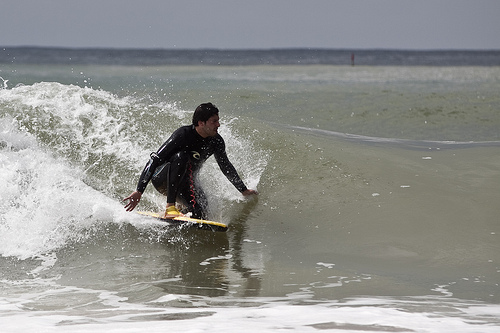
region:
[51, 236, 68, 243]
a drop of water in the ocean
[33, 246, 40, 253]
a drop of water in the ocean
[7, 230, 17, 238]
a drop of water in the ocean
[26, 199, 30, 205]
a drop of water in the ocean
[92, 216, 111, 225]
a drop of water in the ocean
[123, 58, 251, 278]
the man is surfing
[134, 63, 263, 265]
the man is surfing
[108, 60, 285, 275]
the man is surfing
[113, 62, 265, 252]
the man is surfing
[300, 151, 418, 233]
the water is murky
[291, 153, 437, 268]
the water is murky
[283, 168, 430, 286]
the water is murky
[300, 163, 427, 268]
the water is murky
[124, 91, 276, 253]
The man is kneeling on the board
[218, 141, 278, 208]
The man's hand is in the water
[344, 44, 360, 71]
The buoy that is far away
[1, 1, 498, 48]
The sky looks like it is going to rain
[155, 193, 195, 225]
The man is wearing yellow shoes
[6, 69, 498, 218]
the wave the man is riding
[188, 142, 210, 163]
The logo on the wet suit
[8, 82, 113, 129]
The white foam from the wave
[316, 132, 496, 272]
The water is that smooth and calm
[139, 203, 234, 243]
The surfboard is yellow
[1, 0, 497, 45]
blue of daytime sky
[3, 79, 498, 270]
swelling wave in ocean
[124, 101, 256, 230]
kneeling man on surfboard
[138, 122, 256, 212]
black wetsuit on surfer's body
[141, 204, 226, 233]
foot on top of surfboard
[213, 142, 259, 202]
hand of surfer dragging in water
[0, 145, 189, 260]
splashed water created by surfboard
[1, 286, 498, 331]
white sea foam on ocean surface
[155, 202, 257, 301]
reflection of surfer on water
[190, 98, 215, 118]
black hair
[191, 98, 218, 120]
hair is black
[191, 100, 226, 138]
the man has black hair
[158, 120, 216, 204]
man wearing a black suit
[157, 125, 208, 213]
suit is black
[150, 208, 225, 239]
surfboard is yellow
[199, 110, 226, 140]
the face of a man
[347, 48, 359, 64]
a person in the background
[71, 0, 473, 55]
the sky up above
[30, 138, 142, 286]
a wave in the ocean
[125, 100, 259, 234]
a man on a surf board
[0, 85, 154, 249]
a wave in the water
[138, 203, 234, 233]
a yellow surf board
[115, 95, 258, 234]
a man in the water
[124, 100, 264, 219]
man is on surfboard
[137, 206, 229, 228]
surfboard is on the water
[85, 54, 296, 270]
a man in the water